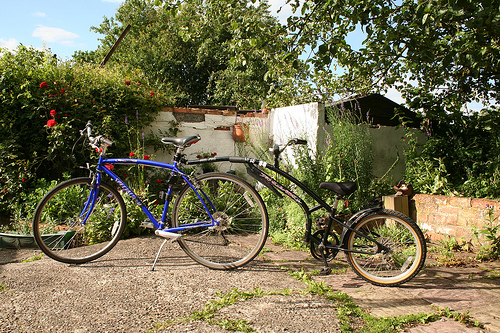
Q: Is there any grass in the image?
A: Yes, there is grass.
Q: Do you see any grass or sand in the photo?
A: Yes, there is grass.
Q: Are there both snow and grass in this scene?
A: No, there is grass but no snow.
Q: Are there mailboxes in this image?
A: No, there are no mailboxes.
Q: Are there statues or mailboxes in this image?
A: No, there are no mailboxes or statues.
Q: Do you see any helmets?
A: No, there are no helmets.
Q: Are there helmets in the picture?
A: No, there are no helmets.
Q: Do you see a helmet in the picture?
A: No, there are no helmets.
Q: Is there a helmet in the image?
A: No, there are no helmets.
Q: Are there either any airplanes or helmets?
A: No, there are no helmets or airplanes.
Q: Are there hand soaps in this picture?
A: No, there are no hand soaps.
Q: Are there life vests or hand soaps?
A: No, there are no hand soaps or life vests.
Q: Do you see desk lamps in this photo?
A: No, there are no desk lamps.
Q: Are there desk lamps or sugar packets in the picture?
A: No, there are no desk lamps or sugar packets.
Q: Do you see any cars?
A: No, there are no cars.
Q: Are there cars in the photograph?
A: No, there are no cars.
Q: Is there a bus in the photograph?
A: No, there are no buses.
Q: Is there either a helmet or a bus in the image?
A: No, there are no buses or helmets.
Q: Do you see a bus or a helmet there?
A: No, there are no buses or helmets.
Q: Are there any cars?
A: No, there are no cars.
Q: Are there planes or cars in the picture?
A: No, there are no cars or planes.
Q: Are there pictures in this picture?
A: No, there are no pictures.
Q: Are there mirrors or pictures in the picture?
A: No, there are no pictures or mirrors.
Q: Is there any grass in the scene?
A: Yes, there is grass.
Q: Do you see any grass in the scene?
A: Yes, there is grass.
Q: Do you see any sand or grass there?
A: Yes, there is grass.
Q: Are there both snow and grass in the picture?
A: No, there is grass but no snow.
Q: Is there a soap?
A: No, there are no soaps.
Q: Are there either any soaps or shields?
A: No, there are no soaps or shields.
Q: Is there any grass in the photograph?
A: Yes, there is grass.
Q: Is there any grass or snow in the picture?
A: Yes, there is grass.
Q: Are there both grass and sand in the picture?
A: No, there is grass but no sand.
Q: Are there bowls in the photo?
A: No, there are no bowls.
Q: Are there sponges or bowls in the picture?
A: No, there are no bowls or sponges.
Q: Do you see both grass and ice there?
A: No, there is grass but no ice.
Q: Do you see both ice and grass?
A: No, there is grass but no ice.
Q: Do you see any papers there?
A: No, there are no papers.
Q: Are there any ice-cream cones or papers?
A: No, there are no papers or ice-cream cones.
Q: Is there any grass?
A: Yes, there is grass.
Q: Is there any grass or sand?
A: Yes, there is grass.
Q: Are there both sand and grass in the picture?
A: No, there is grass but no sand.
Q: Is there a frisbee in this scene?
A: No, there are no frisbees.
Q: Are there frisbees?
A: No, there are no frisbees.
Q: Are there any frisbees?
A: No, there are no frisbees.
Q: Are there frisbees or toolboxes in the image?
A: No, there are no frisbees or toolboxes.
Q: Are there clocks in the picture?
A: No, there are no clocks.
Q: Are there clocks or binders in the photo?
A: No, there are no clocks or binders.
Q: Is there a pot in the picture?
A: Yes, there is a pot.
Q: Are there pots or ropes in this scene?
A: Yes, there is a pot.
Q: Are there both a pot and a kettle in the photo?
A: No, there is a pot but no kettles.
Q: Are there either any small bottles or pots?
A: Yes, there is a small pot.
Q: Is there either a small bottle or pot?
A: Yes, there is a small pot.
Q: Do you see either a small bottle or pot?
A: Yes, there is a small pot.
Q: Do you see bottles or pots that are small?
A: Yes, the pot is small.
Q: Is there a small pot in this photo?
A: Yes, there is a small pot.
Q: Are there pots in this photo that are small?
A: Yes, there is a pot that is small.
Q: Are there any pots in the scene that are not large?
A: Yes, there is a small pot.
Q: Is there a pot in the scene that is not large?
A: Yes, there is a small pot.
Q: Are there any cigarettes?
A: No, there are no cigarettes.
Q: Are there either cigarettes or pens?
A: No, there are no cigarettes or pens.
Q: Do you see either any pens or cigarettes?
A: No, there are no cigarettes or pens.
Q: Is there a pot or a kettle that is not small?
A: No, there is a pot but it is small.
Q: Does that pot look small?
A: Yes, the pot is small.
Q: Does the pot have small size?
A: Yes, the pot is small.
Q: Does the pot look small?
A: Yes, the pot is small.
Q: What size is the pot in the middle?
A: The pot is small.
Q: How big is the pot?
A: The pot is small.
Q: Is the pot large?
A: No, the pot is small.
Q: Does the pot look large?
A: No, the pot is small.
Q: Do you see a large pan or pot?
A: No, there is a pot but it is small.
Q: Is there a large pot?
A: No, there is a pot but it is small.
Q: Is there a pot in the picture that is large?
A: No, there is a pot but it is small.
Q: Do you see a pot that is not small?
A: No, there is a pot but it is small.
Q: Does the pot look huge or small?
A: The pot is small.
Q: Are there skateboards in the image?
A: Yes, there is a skateboard.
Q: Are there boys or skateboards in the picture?
A: Yes, there is a skateboard.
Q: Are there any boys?
A: No, there are no boys.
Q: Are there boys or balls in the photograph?
A: No, there are no boys or balls.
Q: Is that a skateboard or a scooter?
A: That is a skateboard.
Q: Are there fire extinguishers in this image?
A: No, there are no fire extinguishers.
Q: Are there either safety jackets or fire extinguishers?
A: No, there are no fire extinguishers or safety jackets.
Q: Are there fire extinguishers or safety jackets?
A: No, there are no fire extinguishers or safety jackets.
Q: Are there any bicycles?
A: Yes, there is a bicycle.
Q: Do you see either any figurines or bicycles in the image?
A: Yes, there is a bicycle.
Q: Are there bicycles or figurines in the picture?
A: Yes, there is a bicycle.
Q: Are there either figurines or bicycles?
A: Yes, there is a bicycle.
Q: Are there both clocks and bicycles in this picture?
A: No, there is a bicycle but no clocks.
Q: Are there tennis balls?
A: No, there are no tennis balls.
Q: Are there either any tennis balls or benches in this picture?
A: No, there are no tennis balls or benches.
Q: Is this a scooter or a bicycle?
A: This is a bicycle.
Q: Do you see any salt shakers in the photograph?
A: No, there are no salt shakers.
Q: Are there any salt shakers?
A: No, there are no salt shakers.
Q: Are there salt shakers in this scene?
A: No, there are no salt shakers.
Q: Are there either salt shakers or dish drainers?
A: No, there are no salt shakers or dish drainers.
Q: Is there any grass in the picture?
A: Yes, there is grass.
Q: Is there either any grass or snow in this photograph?
A: Yes, there is grass.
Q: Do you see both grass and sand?
A: No, there is grass but no sand.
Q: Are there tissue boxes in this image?
A: No, there are no tissue boxes.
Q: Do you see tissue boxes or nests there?
A: No, there are no tissue boxes or nests.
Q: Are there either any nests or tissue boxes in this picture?
A: No, there are no tissue boxes or nests.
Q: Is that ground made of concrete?
A: Yes, the ground is made of concrete.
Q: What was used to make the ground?
A: The ground is made of cement.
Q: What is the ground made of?
A: The ground is made of concrete.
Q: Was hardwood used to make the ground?
A: No, the ground is made of cement.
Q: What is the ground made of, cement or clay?
A: The ground is made of cement.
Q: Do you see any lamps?
A: No, there are no lamps.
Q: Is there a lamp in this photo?
A: No, there are no lamps.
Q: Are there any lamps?
A: No, there are no lamps.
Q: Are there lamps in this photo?
A: No, there are no lamps.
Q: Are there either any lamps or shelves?
A: No, there are no lamps or shelves.